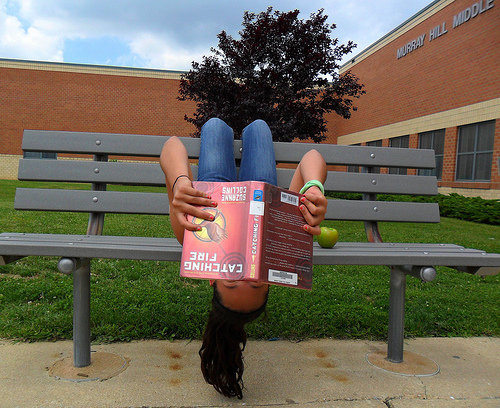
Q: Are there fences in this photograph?
A: No, there are no fences.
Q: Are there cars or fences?
A: No, there are no fences or cars.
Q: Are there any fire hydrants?
A: No, there are no fire hydrants.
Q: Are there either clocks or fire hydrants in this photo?
A: No, there are no fire hydrants or clocks.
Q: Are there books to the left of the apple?
A: Yes, there is a book to the left of the apple.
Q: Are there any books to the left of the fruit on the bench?
A: Yes, there is a book to the left of the apple.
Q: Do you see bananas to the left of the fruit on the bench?
A: No, there is a book to the left of the apple.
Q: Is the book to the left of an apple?
A: Yes, the book is to the left of an apple.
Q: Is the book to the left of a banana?
A: No, the book is to the left of an apple.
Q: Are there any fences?
A: No, there are no fences.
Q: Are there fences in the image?
A: No, there are no fences.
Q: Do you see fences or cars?
A: No, there are no fences or cars.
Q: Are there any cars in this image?
A: No, there are no cars.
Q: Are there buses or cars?
A: No, there are no cars or buses.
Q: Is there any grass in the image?
A: Yes, there is grass.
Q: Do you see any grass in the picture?
A: Yes, there is grass.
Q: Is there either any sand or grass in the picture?
A: Yes, there is grass.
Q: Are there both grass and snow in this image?
A: No, there is grass but no snow.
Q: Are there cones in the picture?
A: No, there are no cones.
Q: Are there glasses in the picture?
A: No, there are no glasses.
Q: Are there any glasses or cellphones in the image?
A: No, there are no glasses or cellphones.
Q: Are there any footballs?
A: No, there are no footballs.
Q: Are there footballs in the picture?
A: No, there are no footballs.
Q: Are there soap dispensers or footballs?
A: No, there are no footballs or soap dispensers.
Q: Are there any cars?
A: No, there are no cars.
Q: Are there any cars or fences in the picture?
A: No, there are no cars or fences.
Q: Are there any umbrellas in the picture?
A: No, there are no umbrellas.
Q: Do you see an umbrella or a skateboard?
A: No, there are no umbrellas or skateboards.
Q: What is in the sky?
A: The clouds are in the sky.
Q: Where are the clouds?
A: The clouds are in the sky.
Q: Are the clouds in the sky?
A: Yes, the clouds are in the sky.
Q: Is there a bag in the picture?
A: No, there are no bags.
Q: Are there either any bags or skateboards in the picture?
A: No, there are no bags or skateboards.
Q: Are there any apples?
A: Yes, there is an apple.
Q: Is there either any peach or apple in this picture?
A: Yes, there is an apple.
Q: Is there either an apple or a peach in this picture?
A: Yes, there is an apple.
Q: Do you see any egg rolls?
A: No, there are no egg rolls.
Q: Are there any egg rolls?
A: No, there are no egg rolls.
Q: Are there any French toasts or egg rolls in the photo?
A: No, there are no egg rolls or French toasts.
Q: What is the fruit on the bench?
A: The fruit is an apple.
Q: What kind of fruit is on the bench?
A: The fruit is an apple.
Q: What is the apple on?
A: The apple is on the bench.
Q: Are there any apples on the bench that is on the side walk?
A: Yes, there is an apple on the bench.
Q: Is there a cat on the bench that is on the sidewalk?
A: No, there is an apple on the bench.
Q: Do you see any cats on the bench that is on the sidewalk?
A: No, there is an apple on the bench.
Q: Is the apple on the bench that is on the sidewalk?
A: Yes, the apple is on the bench.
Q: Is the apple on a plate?
A: No, the apple is on the bench.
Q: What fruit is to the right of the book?
A: The fruit is an apple.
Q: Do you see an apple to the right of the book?
A: Yes, there is an apple to the right of the book.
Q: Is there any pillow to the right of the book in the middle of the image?
A: No, there is an apple to the right of the book.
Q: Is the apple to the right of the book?
A: Yes, the apple is to the right of the book.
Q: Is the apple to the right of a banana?
A: No, the apple is to the right of the book.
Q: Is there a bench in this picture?
A: Yes, there is a bench.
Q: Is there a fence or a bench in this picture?
A: Yes, there is a bench.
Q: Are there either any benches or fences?
A: Yes, there is a bench.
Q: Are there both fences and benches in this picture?
A: No, there is a bench but no fences.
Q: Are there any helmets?
A: No, there are no helmets.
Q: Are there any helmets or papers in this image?
A: No, there are no helmets or papers.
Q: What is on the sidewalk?
A: The bench is on the sidewalk.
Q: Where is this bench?
A: The bench is on the sidewalk.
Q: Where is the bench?
A: The bench is on the sidewalk.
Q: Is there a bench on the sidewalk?
A: Yes, there is a bench on the sidewalk.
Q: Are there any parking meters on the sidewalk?
A: No, there is a bench on the sidewalk.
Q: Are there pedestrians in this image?
A: No, there are no pedestrians.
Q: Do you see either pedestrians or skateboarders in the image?
A: No, there are no pedestrians or skateboarders.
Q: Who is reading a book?
A: The girl is reading a book.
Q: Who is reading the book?
A: The girl is reading a book.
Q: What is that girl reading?
A: The girl is reading a book.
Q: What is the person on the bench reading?
A: The girl is reading a book.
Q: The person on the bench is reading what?
A: The girl is reading a book.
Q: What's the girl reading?
A: The girl is reading a book.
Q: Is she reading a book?
A: Yes, the girl is reading a book.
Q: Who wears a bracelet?
A: The girl wears a bracelet.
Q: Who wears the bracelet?
A: The girl wears a bracelet.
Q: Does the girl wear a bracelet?
A: Yes, the girl wears a bracelet.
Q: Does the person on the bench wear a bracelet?
A: Yes, the girl wears a bracelet.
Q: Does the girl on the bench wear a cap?
A: No, the girl wears a bracelet.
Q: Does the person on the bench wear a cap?
A: No, the girl wears a bracelet.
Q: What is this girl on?
A: The girl is on the bench.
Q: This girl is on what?
A: The girl is on the bench.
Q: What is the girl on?
A: The girl is on the bench.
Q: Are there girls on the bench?
A: Yes, there is a girl on the bench.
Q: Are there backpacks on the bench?
A: No, there is a girl on the bench.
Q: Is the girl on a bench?
A: Yes, the girl is on a bench.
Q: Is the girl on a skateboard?
A: No, the girl is on a bench.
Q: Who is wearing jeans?
A: The girl is wearing jeans.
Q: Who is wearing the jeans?
A: The girl is wearing jeans.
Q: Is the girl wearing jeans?
A: Yes, the girl is wearing jeans.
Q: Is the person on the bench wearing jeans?
A: Yes, the girl is wearing jeans.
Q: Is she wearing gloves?
A: No, the girl is wearing jeans.